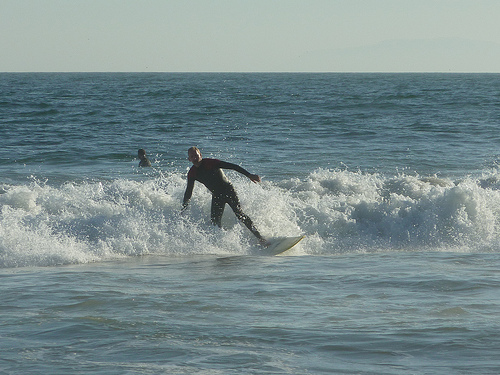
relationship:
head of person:
[134, 146, 148, 157] [133, 146, 155, 168]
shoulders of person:
[137, 154, 152, 167] [133, 146, 155, 168]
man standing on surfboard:
[179, 146, 269, 247] [209, 219, 304, 259]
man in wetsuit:
[179, 146, 269, 247] [191, 160, 235, 212]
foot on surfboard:
[254, 235, 270, 247] [239, 230, 308, 260]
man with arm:
[179, 146, 269, 247] [207, 157, 260, 182]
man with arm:
[179, 146, 269, 247] [183, 171, 195, 213]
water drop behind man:
[169, 162, 174, 167] [179, 146, 269, 247]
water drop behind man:
[205, 136, 210, 138] [179, 146, 269, 247]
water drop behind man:
[237, 162, 242, 166] [179, 146, 269, 247]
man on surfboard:
[179, 145, 269, 247] [247, 233, 304, 255]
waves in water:
[7, 173, 478, 285] [1, 70, 498, 373]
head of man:
[185, 146, 202, 164] [179, 146, 269, 247]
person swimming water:
[132, 144, 152, 172] [1, 70, 498, 373]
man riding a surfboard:
[179, 145, 269, 247] [240, 233, 304, 257]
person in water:
[132, 144, 152, 172] [1, 70, 498, 373]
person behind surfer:
[132, 144, 152, 172] [175, 140, 275, 248]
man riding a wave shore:
[179, 146, 269, 247] [3, 67, 468, 373]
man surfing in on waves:
[179, 146, 269, 247] [0, 164, 499, 268]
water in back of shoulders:
[1, 70, 498, 373] [178, 158, 230, 181]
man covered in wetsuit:
[179, 146, 269, 247] [179, 156, 267, 251]